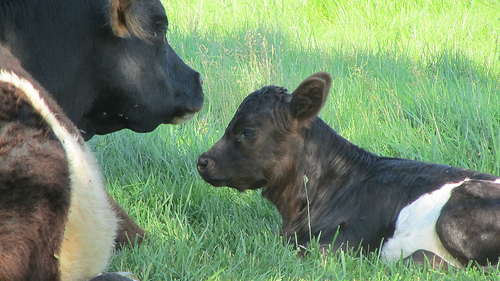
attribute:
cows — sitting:
[2, 2, 490, 270]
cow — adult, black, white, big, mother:
[4, 5, 210, 279]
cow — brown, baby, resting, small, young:
[212, 72, 500, 262]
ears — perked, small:
[276, 67, 329, 127]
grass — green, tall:
[174, 5, 494, 87]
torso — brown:
[1, 54, 122, 279]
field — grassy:
[183, 8, 489, 161]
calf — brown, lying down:
[194, 82, 498, 279]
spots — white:
[346, 175, 470, 274]